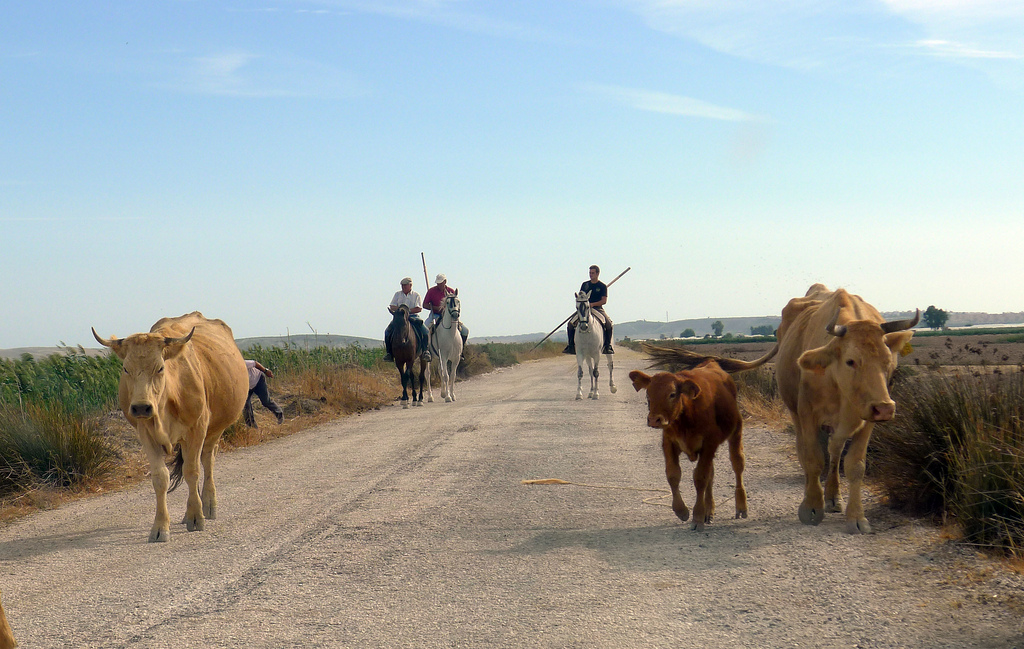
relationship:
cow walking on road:
[80, 302, 270, 538] [11, 291, 1005, 645]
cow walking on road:
[629, 353, 744, 532] [36, 256, 982, 643]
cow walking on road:
[769, 258, 906, 514] [769, 258, 906, 514]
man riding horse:
[539, 251, 622, 391] [571, 284, 623, 405]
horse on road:
[571, 284, 623, 405] [539, 251, 622, 391]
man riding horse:
[411, 271, 497, 392] [411, 271, 497, 392]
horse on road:
[411, 271, 497, 392] [0, 343, 1024, 644]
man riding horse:
[365, 250, 424, 402] [374, 250, 425, 402]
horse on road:
[374, 250, 425, 402] [0, 343, 1024, 644]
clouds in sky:
[144, 70, 227, 143] [1, 3, 1019, 349]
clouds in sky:
[394, 32, 496, 128] [1, 3, 1019, 349]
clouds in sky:
[658, 84, 756, 154] [1, 3, 1019, 349]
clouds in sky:
[829, 176, 925, 244] [1, 3, 1019, 349]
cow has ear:
[646, 278, 921, 533] [801, 336, 834, 369]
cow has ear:
[646, 278, 921, 533] [880, 318, 915, 357]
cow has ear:
[629, 353, 744, 532] [677, 377, 710, 394]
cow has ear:
[623, 353, 749, 526] [629, 365, 658, 386]